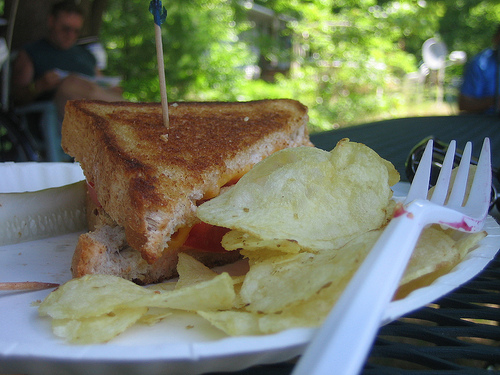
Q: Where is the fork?
A: On the plate.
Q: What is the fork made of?
A: Plastic.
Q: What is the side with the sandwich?
A: Chips.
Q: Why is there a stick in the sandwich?
A: Decoration.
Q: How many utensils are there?
A: 1.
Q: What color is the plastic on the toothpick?
A: Blue.